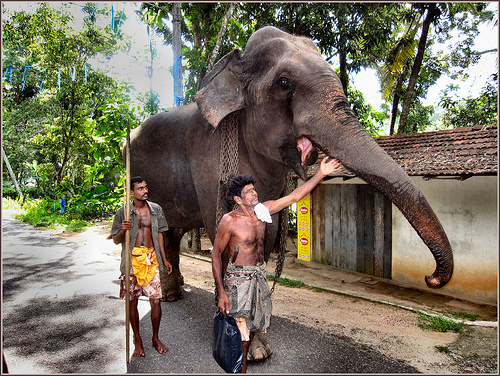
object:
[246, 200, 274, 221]
shirt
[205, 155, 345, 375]
man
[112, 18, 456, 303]
elephant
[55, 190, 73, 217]
flag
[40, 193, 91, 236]
weed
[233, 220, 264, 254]
chest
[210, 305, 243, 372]
bag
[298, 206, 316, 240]
sign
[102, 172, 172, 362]
person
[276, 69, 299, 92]
eye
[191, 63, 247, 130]
ear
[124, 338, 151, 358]
feet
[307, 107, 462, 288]
trunk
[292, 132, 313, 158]
tongue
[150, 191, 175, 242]
shirt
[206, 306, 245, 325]
string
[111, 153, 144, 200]
handle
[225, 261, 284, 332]
short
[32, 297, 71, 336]
shadow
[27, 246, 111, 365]
ground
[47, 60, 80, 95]
leave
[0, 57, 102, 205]
tree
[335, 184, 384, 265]
panel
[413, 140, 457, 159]
roof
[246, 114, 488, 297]
building